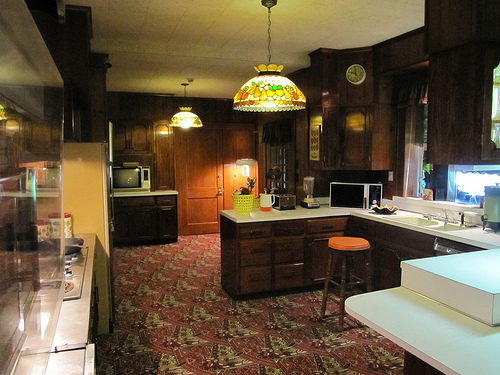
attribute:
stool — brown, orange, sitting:
[315, 234, 376, 338]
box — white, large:
[394, 242, 499, 329]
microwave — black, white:
[325, 178, 387, 212]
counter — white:
[215, 199, 499, 374]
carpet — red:
[99, 231, 413, 375]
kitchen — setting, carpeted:
[1, 2, 497, 373]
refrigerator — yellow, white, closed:
[60, 138, 115, 342]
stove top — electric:
[54, 244, 93, 303]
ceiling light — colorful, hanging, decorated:
[230, 60, 311, 117]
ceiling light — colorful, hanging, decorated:
[164, 103, 205, 132]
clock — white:
[344, 62, 369, 86]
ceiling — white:
[56, 0, 432, 106]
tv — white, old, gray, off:
[109, 162, 153, 195]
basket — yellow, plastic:
[230, 191, 255, 215]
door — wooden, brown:
[165, 118, 264, 240]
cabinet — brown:
[303, 233, 348, 287]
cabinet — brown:
[111, 207, 158, 249]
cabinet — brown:
[330, 105, 376, 171]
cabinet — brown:
[366, 239, 403, 289]